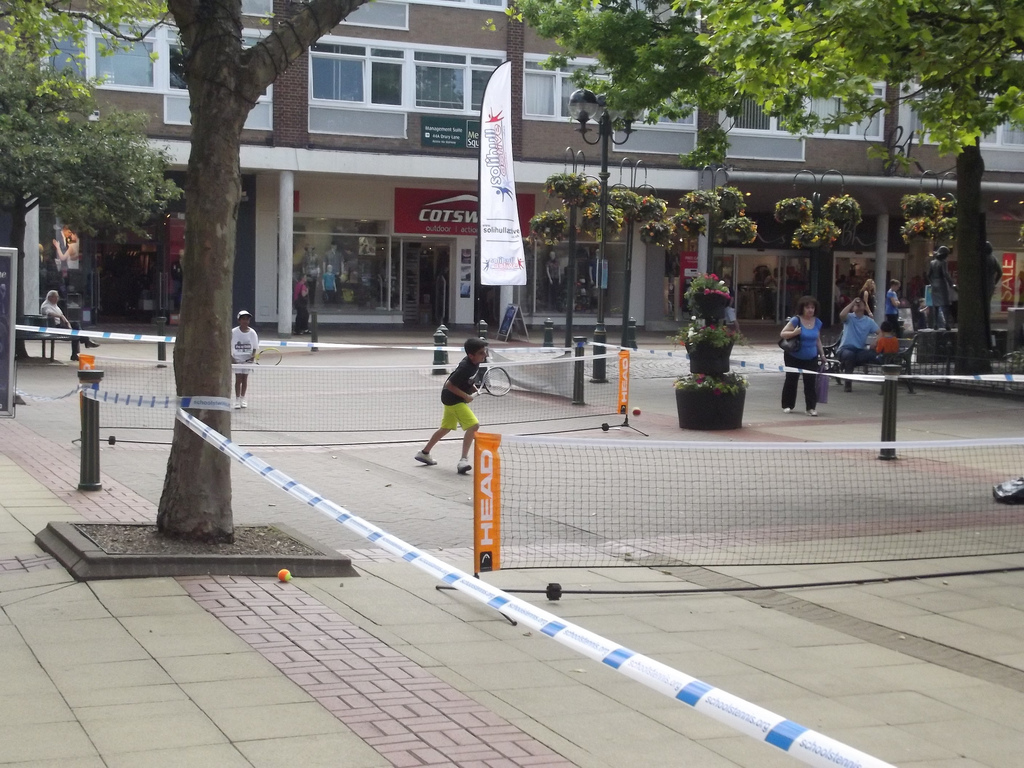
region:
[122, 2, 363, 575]
a large tree trunk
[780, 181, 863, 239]
flowers are hanging outside the buildings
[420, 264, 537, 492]
Young boy with tennis racket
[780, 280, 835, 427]
Woman walking with purse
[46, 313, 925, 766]
area taped off with blue and white tape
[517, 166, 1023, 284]
Flowers hanging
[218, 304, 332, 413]
Man playing tennis outside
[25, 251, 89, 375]
Woman sitting on the park bench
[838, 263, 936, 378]
Man watching tennis game outside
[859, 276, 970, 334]
People walking down the street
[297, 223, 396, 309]
People inside the store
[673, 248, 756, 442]
Flowers sitting in the middle of the concrete area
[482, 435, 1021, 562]
a tennis net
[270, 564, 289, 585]
a tennis ball lies on the ground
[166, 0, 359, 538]
a tree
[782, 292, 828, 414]
a woman carrying a purse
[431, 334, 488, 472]
a boy with a tennis racket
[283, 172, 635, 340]
a storefront in the background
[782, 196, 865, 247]
hanging flower pots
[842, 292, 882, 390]
a man is sitting on a bench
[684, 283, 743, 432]
stacked flower pots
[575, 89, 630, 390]
a lamp post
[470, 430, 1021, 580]
net with orange end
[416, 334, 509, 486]
kid in yellow shorts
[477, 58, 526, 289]
white banner with words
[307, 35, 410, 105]
open window above shop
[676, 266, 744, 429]
two tiered plant in pot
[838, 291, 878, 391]
man sitting wearing blue tee shrt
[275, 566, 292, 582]
orange and yellow tennis ball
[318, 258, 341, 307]
mannequin in store window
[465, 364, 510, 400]
tennis racket in boy's hand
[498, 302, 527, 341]
sandwich board outside store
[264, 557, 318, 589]
Yellow and green tennis ball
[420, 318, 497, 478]
Boy wearing yellow shorts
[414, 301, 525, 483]
Boy holding a tennis racket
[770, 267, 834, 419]
Lady wearing blue shirt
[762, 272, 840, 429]
Lady carrying purse and bag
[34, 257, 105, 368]
Man sitting on bench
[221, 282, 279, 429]
Someone wearing a white cap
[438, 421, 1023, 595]
Tennis net with orange trimming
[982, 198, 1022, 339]
Red and white sign in window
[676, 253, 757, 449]
Three plants stacked on top of eachother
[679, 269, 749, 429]
three pots containing plants on top of each other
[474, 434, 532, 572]
orange border on fence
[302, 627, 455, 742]
section of ground paved with bricks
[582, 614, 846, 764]
blue and white striped temporary barrier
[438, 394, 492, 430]
boy wearing yellow shorts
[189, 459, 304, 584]
orange and white tennis ball near tree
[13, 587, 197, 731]
ground paved with large square blocks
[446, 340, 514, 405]
boy holding racket in right hand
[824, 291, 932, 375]
man sitting on bench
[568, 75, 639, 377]
double lamp partially hidden by tree leaves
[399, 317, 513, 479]
A boy playing tennis in the street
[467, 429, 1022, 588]
a tennis net in the street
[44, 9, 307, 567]
a tree in a sidewalk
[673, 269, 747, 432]
3 planters stacked on top of eachother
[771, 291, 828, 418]
a woman walking with a purse and a bag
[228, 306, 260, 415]
a boy playing tennis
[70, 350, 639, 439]
a tennis net set up in a street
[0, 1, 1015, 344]
a building with stores